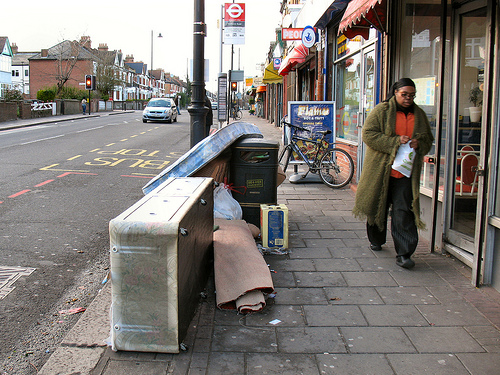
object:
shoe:
[394, 255, 417, 269]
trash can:
[232, 137, 280, 230]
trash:
[259, 203, 288, 249]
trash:
[103, 175, 216, 356]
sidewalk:
[37, 110, 499, 374]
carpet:
[209, 218, 274, 317]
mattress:
[137, 119, 263, 199]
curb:
[37, 275, 114, 375]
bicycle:
[277, 114, 354, 190]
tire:
[316, 148, 354, 189]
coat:
[351, 96, 435, 234]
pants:
[365, 174, 420, 259]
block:
[240, 351, 322, 375]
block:
[450, 352, 500, 375]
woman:
[348, 77, 434, 269]